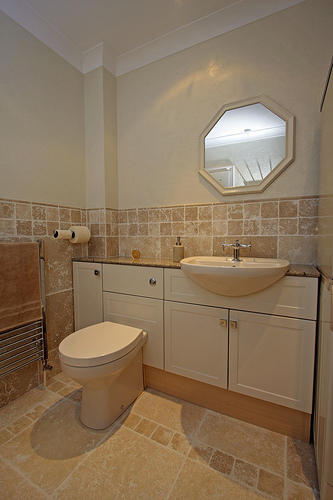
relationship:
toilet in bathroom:
[50, 301, 167, 430] [2, 0, 328, 303]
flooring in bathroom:
[18, 431, 253, 483] [3, 71, 321, 429]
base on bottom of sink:
[143, 365, 310, 440] [72, 238, 321, 443]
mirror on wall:
[196, 93, 296, 194] [117, 0, 329, 263]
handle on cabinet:
[218, 317, 226, 327] [163, 262, 323, 444]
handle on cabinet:
[229, 320, 238, 329] [163, 262, 323, 444]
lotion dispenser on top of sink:
[172, 234, 185, 264] [181, 239, 289, 297]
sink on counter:
[179, 254, 290, 295] [71, 254, 320, 278]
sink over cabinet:
[179, 254, 290, 295] [160, 296, 316, 417]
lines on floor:
[112, 416, 293, 498] [0, 368, 318, 496]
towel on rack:
[0, 240, 42, 332] [0, 243, 42, 376]